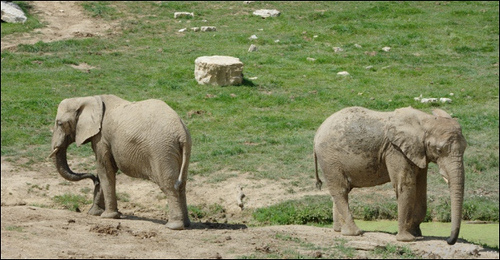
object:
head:
[46, 97, 104, 187]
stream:
[323, 219, 500, 250]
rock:
[337, 70, 350, 75]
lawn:
[260, 6, 487, 97]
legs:
[96, 158, 120, 219]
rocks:
[248, 45, 257, 52]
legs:
[154, 180, 189, 229]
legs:
[326, 184, 361, 236]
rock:
[413, 92, 455, 104]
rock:
[0, 1, 27, 24]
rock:
[172, 11, 194, 18]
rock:
[252, 8, 280, 18]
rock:
[178, 25, 214, 33]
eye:
[58, 123, 63, 125]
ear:
[75, 95, 104, 147]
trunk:
[47, 133, 100, 186]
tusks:
[48, 147, 59, 158]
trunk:
[437, 157, 465, 245]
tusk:
[441, 175, 448, 183]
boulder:
[195, 56, 244, 87]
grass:
[348, 38, 458, 79]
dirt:
[29, 202, 136, 252]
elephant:
[312, 106, 466, 245]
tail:
[313, 154, 322, 190]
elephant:
[47, 94, 192, 230]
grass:
[112, 52, 189, 97]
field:
[0, 0, 499, 260]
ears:
[384, 107, 427, 169]